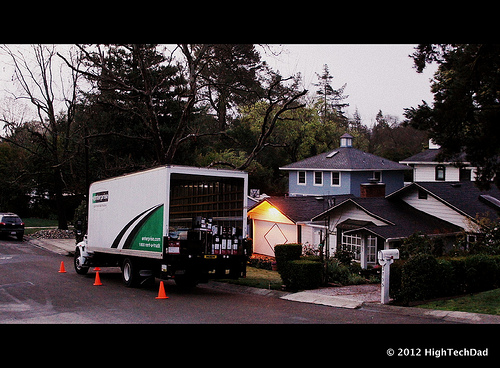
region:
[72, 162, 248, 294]
partially loaded moving van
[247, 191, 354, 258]
garage with security light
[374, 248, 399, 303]
white mailbox on wooden post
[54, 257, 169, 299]
orange safety traffic cones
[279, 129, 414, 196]
blue and white 2-story home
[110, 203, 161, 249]
green, black, and white stripes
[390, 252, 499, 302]
row of trimmed hedges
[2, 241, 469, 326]
residential city street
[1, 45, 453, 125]
gray and dreary sky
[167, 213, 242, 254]
materials loaded in truck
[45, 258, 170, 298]
Orange traffic cones on a street.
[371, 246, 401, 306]
White mailbox next to a street.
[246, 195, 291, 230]
House light turned on.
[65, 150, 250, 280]
Open moving truck on a street.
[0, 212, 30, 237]
Black car on the side of a street.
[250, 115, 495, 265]
Large blue house.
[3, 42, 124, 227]
Tree without leaves in a yard.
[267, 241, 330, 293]
Green bushes by a house.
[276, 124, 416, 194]
Roof on a blue house.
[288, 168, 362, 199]
Windows on a blue house.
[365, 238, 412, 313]
A white mailbox and post.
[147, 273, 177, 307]
A medium sized orange cone.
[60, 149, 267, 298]
White moving van.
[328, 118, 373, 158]
Top spire of a house.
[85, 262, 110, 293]
Small orange cone.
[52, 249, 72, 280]
Small orange cone.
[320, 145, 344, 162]
Glass sky light.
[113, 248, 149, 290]
Rubber truck tire and rim.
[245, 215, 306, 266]
White garage door with design.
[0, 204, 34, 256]
Black SUV vehicle.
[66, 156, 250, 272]
This is a moving truck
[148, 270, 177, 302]
This is an orange cone.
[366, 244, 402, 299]
This is a mail box.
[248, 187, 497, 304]
This is a home.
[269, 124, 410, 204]
This is a blue house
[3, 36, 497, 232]
This is a forest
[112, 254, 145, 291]
This is a tire.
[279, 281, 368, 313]
This is a driveway.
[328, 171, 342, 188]
This is a window.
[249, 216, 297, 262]
This is a garage door.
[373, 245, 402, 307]
White mailbox on a post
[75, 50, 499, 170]
Tall trees behind the house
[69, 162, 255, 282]
Mid-sized moving van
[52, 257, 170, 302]
Three traffic cones in the street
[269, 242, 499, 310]
Shrubs line the driveway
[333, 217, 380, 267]
Multi-pane picture window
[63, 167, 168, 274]
Moving van is white, green, and black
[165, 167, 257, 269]
Items visible at the back of open moving van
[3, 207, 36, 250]
Car is parked on the street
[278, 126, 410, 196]
House painted blue